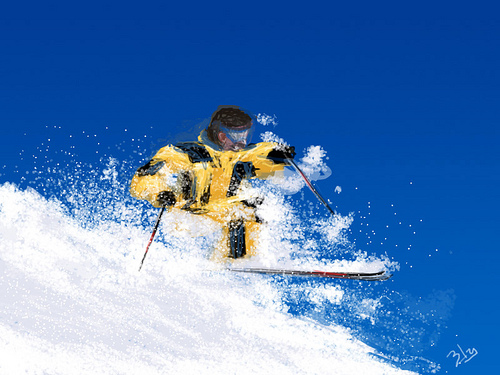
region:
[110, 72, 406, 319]
person skiing on snowy mountain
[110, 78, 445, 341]
man skiing on snowy mountain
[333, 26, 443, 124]
The sky is blue.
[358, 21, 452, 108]
The sky is clear.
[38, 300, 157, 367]
The snow is white.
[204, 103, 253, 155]
The man has brown hair.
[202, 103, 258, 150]
The man has short hair.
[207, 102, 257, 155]
The man is wearing goggles.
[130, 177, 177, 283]
The man is holding a ski pole.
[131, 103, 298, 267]
The man's clothing is yellow and black.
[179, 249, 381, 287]
The man is wearing skis.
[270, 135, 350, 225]
The man is holding a ski pole.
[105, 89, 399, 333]
A skier coming down fast on a slope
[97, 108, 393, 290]
a skier skiing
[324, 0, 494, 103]
a bright blue sky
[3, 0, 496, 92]
a cloud less sky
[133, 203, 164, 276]
a red and black ski pole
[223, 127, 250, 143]
blue goggles on a face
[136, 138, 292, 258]
a black and yellow ski suite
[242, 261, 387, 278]
a red and black skis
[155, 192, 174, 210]
a right gloved hand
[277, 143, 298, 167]
a left gloved hand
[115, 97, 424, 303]
a skier making a jump